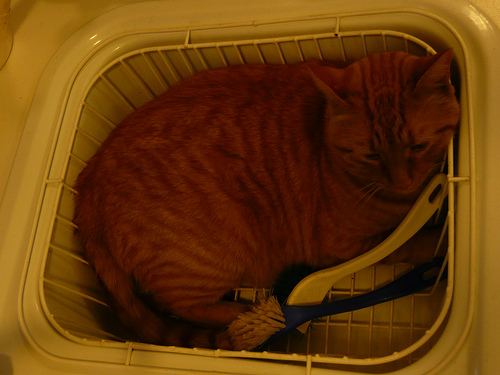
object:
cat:
[72, 47, 466, 350]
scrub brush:
[224, 254, 452, 352]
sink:
[4, 1, 499, 374]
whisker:
[350, 181, 385, 212]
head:
[305, 46, 461, 195]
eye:
[353, 147, 382, 166]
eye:
[403, 138, 428, 155]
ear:
[303, 61, 352, 106]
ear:
[416, 48, 453, 90]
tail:
[79, 231, 237, 348]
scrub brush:
[269, 171, 450, 339]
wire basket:
[18, 11, 481, 375]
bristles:
[226, 297, 288, 351]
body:
[92, 60, 341, 298]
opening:
[424, 183, 443, 205]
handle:
[332, 169, 450, 281]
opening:
[416, 264, 439, 280]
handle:
[314, 251, 450, 319]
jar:
[0, 0, 22, 78]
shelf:
[0, 3, 20, 375]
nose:
[382, 171, 412, 194]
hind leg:
[126, 242, 258, 331]